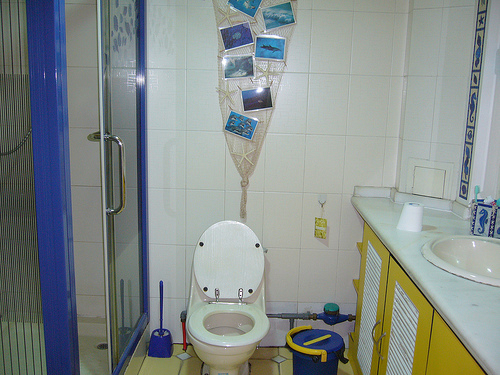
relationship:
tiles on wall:
[302, 68, 390, 141] [144, 1, 444, 344]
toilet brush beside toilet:
[146, 280, 173, 358] [183, 217, 269, 373]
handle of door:
[100, 132, 126, 216] [97, 0, 149, 373]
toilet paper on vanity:
[394, 200, 424, 234] [343, 184, 498, 374]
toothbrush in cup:
[403, 157, 495, 208] [468, 204, 499, 235]